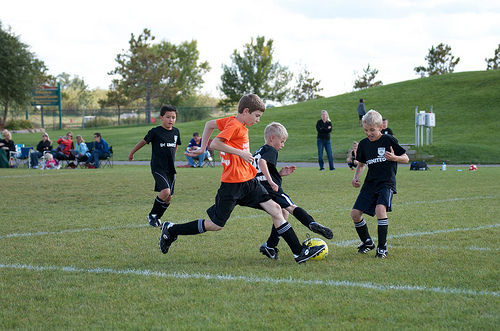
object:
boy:
[127, 105, 182, 227]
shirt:
[144, 125, 182, 173]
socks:
[354, 217, 389, 250]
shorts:
[352, 184, 394, 217]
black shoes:
[357, 242, 389, 259]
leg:
[246, 190, 315, 253]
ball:
[302, 237, 329, 260]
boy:
[158, 93, 332, 264]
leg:
[375, 188, 390, 246]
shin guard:
[377, 218, 388, 250]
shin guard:
[354, 218, 373, 245]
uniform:
[353, 134, 407, 217]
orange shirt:
[216, 115, 258, 183]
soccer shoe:
[374, 247, 388, 259]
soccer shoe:
[357, 242, 376, 254]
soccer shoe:
[293, 244, 326, 265]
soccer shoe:
[259, 242, 280, 260]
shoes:
[157, 221, 388, 265]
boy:
[250, 122, 333, 261]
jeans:
[317, 138, 334, 170]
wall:
[114, 69, 500, 165]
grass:
[0, 69, 500, 331]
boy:
[349, 109, 409, 258]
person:
[316, 109, 336, 171]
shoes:
[146, 212, 178, 254]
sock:
[168, 219, 206, 239]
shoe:
[157, 222, 177, 256]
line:
[0, 197, 500, 298]